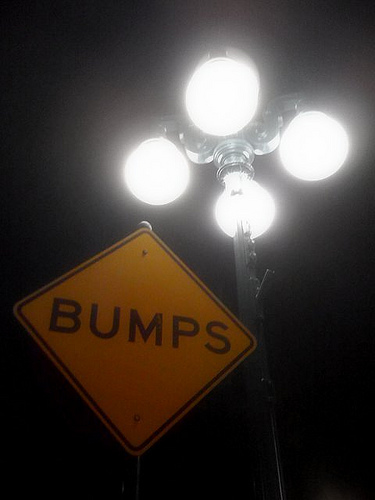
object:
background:
[0, 0, 375, 499]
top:
[137, 218, 152, 231]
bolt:
[132, 412, 141, 421]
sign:
[13, 225, 257, 461]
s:
[203, 319, 232, 355]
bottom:
[110, 423, 165, 460]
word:
[46, 293, 234, 358]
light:
[275, 106, 349, 184]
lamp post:
[234, 223, 292, 500]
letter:
[169, 313, 198, 352]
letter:
[125, 306, 163, 349]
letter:
[89, 299, 121, 343]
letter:
[48, 295, 82, 336]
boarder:
[12, 228, 258, 463]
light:
[212, 174, 276, 243]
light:
[181, 50, 265, 141]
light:
[117, 131, 195, 216]